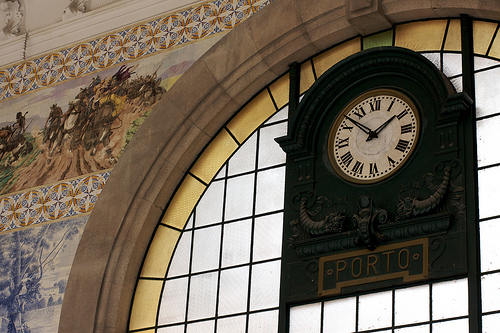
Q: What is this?
A: Clock.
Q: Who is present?
A: No one.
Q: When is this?
A: Daytime.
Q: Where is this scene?
A: In a historic building.